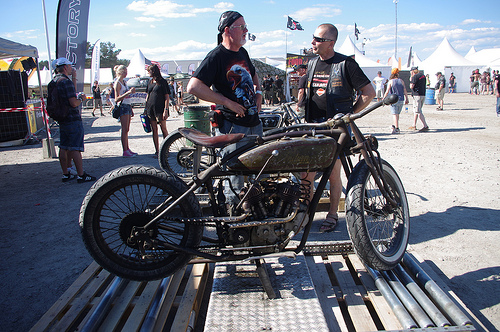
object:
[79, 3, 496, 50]
sky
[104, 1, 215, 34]
clouds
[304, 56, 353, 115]
vest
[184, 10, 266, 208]
man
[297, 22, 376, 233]
man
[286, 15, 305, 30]
flag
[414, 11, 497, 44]
sky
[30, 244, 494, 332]
structure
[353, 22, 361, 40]
flag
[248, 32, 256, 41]
flag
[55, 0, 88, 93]
banner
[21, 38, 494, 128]
crowd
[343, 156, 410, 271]
front tire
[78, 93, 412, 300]
motorbike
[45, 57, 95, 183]
man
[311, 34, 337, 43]
spectacle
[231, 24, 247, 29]
spectacle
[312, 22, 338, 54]
head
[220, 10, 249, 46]
head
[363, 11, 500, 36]
clouds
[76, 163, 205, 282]
tire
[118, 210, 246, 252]
chain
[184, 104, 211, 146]
drum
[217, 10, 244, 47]
bandana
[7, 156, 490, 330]
area